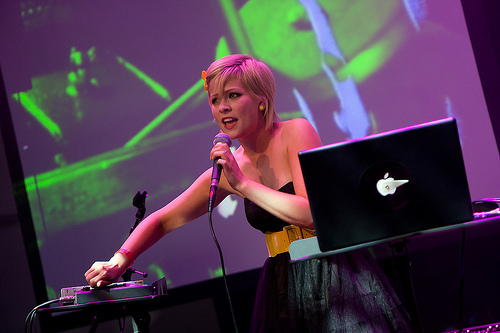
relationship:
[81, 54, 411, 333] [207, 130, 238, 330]
girl holding microphone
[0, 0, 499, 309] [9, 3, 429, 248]
screen has grafitti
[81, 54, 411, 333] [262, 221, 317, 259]
girl wearing belt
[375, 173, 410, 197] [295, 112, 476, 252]
logo on a computer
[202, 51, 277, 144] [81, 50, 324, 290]
head of a girl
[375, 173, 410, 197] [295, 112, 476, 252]
logo on back of computer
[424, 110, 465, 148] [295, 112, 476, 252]
corner of computer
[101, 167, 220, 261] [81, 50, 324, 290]
arm of girl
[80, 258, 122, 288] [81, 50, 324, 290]
hand of girl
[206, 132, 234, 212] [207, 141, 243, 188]
mic in hand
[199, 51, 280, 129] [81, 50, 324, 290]
hair on girl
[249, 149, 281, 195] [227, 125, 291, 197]
shadow on chest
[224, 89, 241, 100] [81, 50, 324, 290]
eye of girl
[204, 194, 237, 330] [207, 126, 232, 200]
cord of microphone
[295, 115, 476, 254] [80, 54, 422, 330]
computer next to woman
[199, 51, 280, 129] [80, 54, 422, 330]
hair on woman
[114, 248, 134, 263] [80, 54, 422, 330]
band on woman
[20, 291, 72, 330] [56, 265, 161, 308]
cable coming from machine